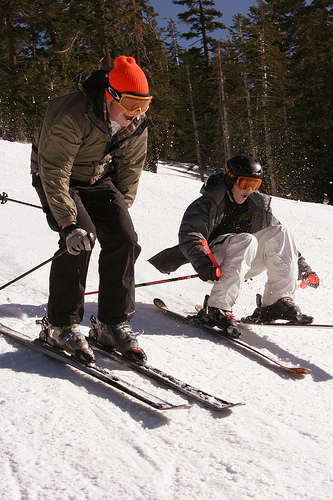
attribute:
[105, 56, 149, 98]
beanie — bright, knit, orange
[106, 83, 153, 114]
goggle — orange, black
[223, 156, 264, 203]
helmet — hard, black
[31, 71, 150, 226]
jacket — green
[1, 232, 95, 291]
pole — black, here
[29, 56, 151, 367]
man — here, skiing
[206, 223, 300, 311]
pants — white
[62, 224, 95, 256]
glove — gray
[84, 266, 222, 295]
pole — orange, black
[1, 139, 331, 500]
trail — here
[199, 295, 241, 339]
boot — gray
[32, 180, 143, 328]
pants — black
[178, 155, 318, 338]
man — crouching, skiing, here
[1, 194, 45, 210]
pole — black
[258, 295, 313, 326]
boot — here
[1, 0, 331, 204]
trees — here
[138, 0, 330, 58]
sky — clear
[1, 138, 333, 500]
snow — here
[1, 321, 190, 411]
ski — black